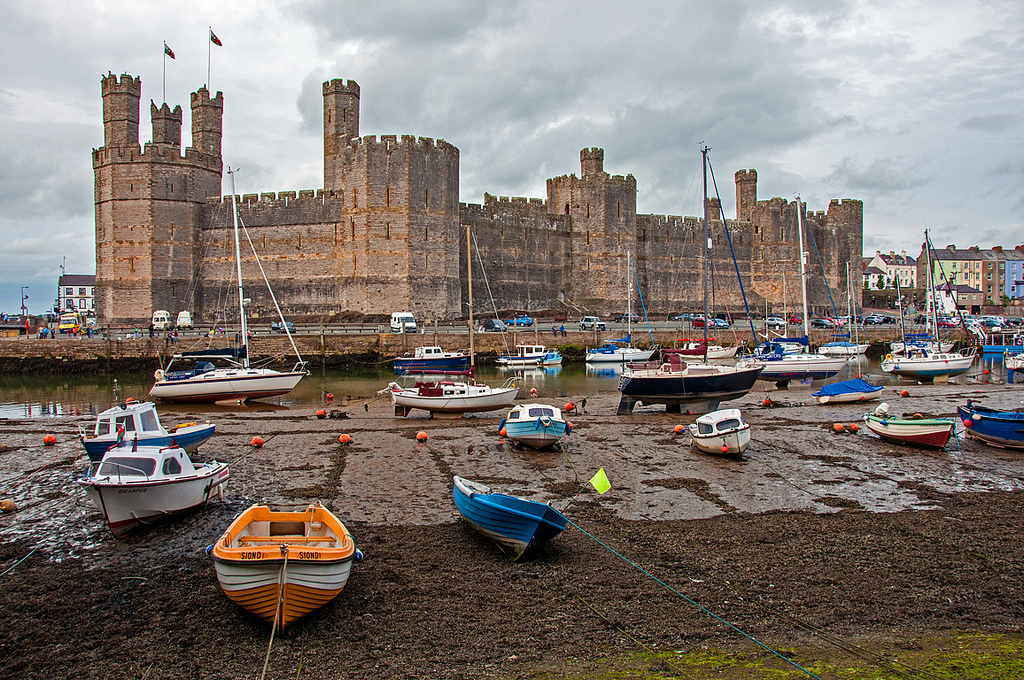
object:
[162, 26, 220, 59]
two flags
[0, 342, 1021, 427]
water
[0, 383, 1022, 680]
ground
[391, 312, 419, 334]
van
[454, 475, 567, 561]
blue boat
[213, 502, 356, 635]
boat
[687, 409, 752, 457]
boat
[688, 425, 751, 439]
stripe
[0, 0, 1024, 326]
background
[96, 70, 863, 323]
building